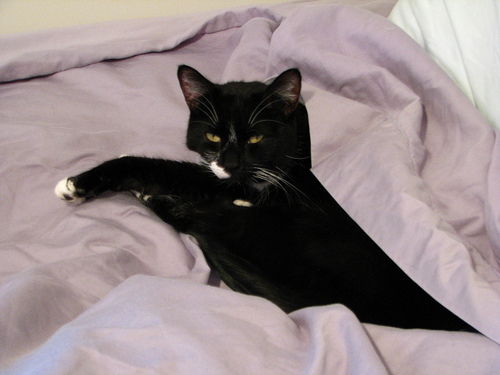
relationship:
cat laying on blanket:
[54, 62, 479, 334] [1, 3, 499, 373]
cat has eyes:
[54, 62, 479, 334] [202, 128, 265, 146]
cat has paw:
[54, 62, 479, 334] [51, 170, 99, 206]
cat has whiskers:
[54, 62, 479, 334] [248, 160, 321, 213]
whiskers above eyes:
[181, 86, 299, 127] [202, 128, 265, 146]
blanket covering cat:
[1, 3, 499, 373] [54, 62, 479, 334]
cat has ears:
[54, 62, 479, 334] [175, 64, 303, 111]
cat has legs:
[54, 62, 479, 334] [49, 154, 222, 238]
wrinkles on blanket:
[51, 208, 142, 278] [1, 3, 499, 373]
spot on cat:
[209, 160, 231, 179] [54, 62, 479, 334]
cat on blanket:
[54, 62, 479, 334] [1, 3, 499, 373]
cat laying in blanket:
[54, 62, 479, 334] [1, 3, 499, 373]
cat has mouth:
[54, 62, 479, 334] [215, 169, 256, 186]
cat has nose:
[54, 62, 479, 334] [223, 163, 242, 174]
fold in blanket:
[3, 10, 279, 80] [1, 3, 499, 373]